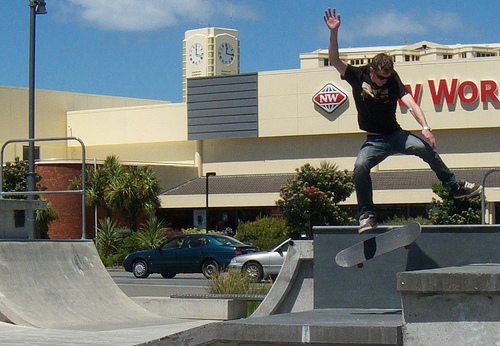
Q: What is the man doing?
A: Riding a skateboard.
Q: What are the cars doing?
A: Driving down the street.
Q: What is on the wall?
A: Signs.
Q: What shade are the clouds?
A: Blue.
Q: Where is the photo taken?
A: At a skate park.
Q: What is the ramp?
A: A skateboarding trick.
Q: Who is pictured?
A: A man.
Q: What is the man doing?
A: Skateboarding.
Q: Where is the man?
A: Skate park.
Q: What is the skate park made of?
A: Concrete.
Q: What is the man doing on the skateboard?
A: A trick.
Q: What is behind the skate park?
A: Parking lot.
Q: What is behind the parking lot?
A: A store.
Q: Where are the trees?
A: In the parking lot.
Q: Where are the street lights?
A: In the parking lot.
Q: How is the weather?
A: Partly cloudy.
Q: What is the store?
A: White.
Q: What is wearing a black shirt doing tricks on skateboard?
A: The guy.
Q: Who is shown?
A: A young man.